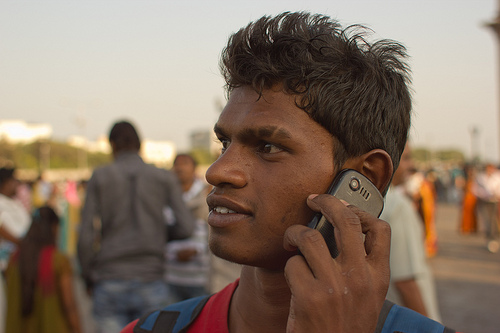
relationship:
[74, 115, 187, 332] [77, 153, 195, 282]
man wearing grey shirt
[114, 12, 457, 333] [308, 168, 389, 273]
man holding cellphone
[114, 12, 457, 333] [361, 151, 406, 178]
man has ear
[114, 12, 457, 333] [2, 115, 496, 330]
man near background people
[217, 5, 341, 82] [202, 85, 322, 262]
hair away from face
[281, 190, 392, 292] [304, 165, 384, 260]
fingers are around cellphone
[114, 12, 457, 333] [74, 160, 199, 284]
man wearing grey shirt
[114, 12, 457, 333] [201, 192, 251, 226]
man relaxed lips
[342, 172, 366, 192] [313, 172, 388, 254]
button on cellphone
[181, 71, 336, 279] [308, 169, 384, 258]
man holding cellphone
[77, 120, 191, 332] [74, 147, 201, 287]
man wearing shirt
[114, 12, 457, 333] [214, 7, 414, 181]
man has hair